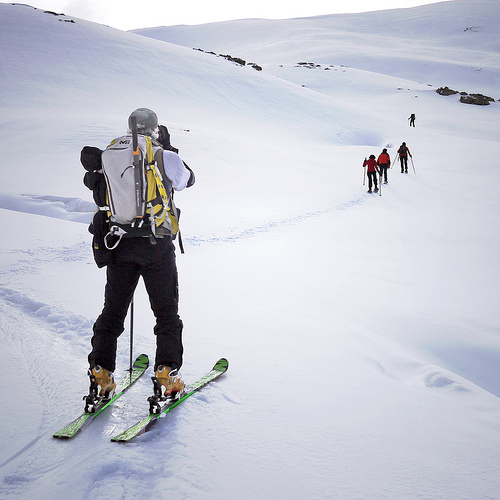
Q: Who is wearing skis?
A: The skier is wearing skis.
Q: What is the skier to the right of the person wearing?
A: The skier is wearing skis.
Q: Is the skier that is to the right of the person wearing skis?
A: Yes, the skier is wearing skis.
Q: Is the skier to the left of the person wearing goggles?
A: No, the skier is wearing skis.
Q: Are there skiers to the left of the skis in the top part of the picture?
A: Yes, there is a skier to the left of the skis.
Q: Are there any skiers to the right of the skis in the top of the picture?
A: No, the skier is to the left of the skis.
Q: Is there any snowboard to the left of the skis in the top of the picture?
A: No, there is a skier to the left of the skis.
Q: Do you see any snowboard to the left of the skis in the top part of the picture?
A: No, there is a skier to the left of the skis.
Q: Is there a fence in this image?
A: No, there are no fences.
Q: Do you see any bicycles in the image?
A: No, there are no bicycles.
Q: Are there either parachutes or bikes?
A: No, there are no bikes or parachutes.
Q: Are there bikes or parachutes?
A: No, there are no bikes or parachutes.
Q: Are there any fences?
A: No, there are no fences.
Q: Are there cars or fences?
A: No, there are no fences or cars.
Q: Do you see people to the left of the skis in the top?
A: Yes, there is a person to the left of the skis.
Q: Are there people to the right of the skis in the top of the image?
A: No, the person is to the left of the skis.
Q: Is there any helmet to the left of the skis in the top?
A: No, there is a person to the left of the skis.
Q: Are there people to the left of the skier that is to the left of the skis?
A: Yes, there is a person to the left of the skier.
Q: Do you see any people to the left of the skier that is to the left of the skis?
A: Yes, there is a person to the left of the skier.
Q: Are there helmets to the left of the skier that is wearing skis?
A: No, there is a person to the left of the skier.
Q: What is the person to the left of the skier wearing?
A: The person is wearing skis.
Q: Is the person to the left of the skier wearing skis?
A: Yes, the person is wearing skis.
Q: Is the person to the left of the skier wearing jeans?
A: No, the person is wearing skis.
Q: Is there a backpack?
A: Yes, there is a backpack.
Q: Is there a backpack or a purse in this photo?
A: Yes, there is a backpack.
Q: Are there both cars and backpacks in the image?
A: No, there is a backpack but no cars.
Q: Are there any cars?
A: No, there are no cars.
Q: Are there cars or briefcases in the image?
A: No, there are no cars or briefcases.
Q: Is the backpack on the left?
A: Yes, the backpack is on the left of the image.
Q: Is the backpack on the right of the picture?
A: No, the backpack is on the left of the image.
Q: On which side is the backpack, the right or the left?
A: The backpack is on the left of the image.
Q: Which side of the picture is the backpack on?
A: The backpack is on the left of the image.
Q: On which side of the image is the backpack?
A: The backpack is on the left of the image.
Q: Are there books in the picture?
A: No, there are no books.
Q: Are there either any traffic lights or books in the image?
A: No, there are no books or traffic lights.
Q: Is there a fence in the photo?
A: No, there are no fences.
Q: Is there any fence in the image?
A: No, there are no fences.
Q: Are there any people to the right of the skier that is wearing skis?
A: Yes, there is a person to the right of the skier.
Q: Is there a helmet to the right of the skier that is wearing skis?
A: No, there is a person to the right of the skier.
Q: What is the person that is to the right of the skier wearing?
A: The person is wearing skis.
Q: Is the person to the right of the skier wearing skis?
A: Yes, the person is wearing skis.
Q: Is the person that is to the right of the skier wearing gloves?
A: No, the person is wearing skis.